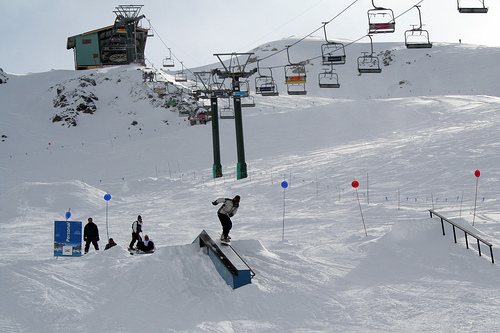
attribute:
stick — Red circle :
[336, 167, 371, 280]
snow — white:
[16, 262, 279, 331]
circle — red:
[350, 179, 360, 187]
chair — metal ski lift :
[277, 74, 312, 101]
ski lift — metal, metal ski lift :
[126, 0, 497, 124]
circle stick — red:
[465, 166, 483, 230]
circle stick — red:
[350, 174, 374, 241]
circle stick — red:
[277, 177, 291, 244]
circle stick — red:
[98, 189, 116, 246]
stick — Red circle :
[345, 177, 372, 242]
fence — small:
[426, 205, 496, 265]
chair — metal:
[164, 50, 173, 67]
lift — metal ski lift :
[356, 52, 385, 76]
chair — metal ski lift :
[253, 72, 280, 95]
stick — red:
[349, 174, 368, 238]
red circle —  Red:
[346, 178, 368, 193]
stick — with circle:
[349, 190, 379, 239]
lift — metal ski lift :
[249, 77, 278, 97]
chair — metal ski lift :
[229, 75, 252, 105]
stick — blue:
[279, 177, 290, 244]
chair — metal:
[279, 58, 306, 96]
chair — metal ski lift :
[316, 67, 346, 91]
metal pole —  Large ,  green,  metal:
[228, 94, 249, 181]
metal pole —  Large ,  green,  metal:
[207, 97, 224, 179]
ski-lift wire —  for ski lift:
[252, 2, 359, 64]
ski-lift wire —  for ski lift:
[261, 2, 423, 73]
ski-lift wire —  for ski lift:
[140, 11, 195, 79]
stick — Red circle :
[345, 172, 375, 241]